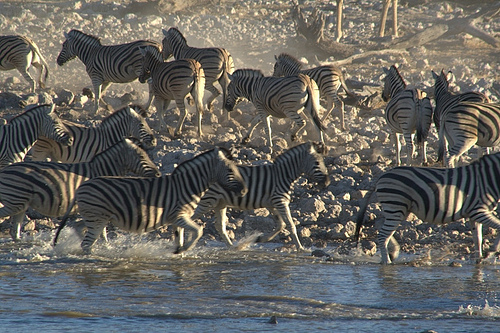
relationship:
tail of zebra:
[344, 181, 376, 249] [348, 145, 498, 276]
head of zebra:
[297, 139, 333, 193] [233, 131, 354, 258]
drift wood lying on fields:
[299, 11, 499, 65] [1, 0, 499, 260]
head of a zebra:
[297, 139, 329, 188] [232, 140, 354, 254]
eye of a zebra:
[306, 158, 324, 172] [226, 129, 352, 262]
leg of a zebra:
[271, 199, 311, 254] [243, 129, 343, 226]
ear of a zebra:
[208, 141, 232, 169] [55, 126, 269, 267]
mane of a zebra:
[168, 153, 210, 183] [58, 144, 272, 283]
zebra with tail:
[127, 46, 216, 145] [188, 73, 213, 117]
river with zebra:
[25, 245, 403, 330] [77, 137, 250, 272]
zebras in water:
[0, 137, 161, 241] [5, 259, 496, 333]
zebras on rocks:
[9, 72, 492, 239] [299, 184, 354, 234]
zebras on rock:
[0, 137, 161, 241] [301, 196, 328, 212]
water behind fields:
[13, 248, 499, 333] [1, 110, 498, 260]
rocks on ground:
[295, 180, 375, 220] [6, 99, 493, 246]